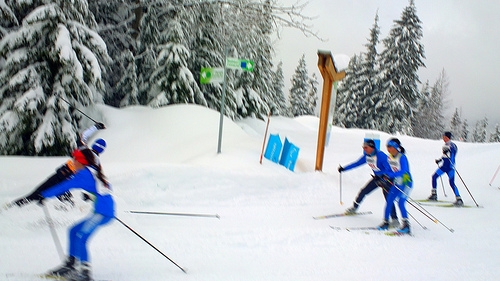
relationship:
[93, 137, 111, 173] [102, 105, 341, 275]
man falling in snow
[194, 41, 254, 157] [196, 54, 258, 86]
post with signs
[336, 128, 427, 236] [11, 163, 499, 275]
skiers on flat ground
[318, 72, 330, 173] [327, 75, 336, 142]
post with hanging sign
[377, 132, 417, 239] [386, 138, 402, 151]
skiier has blue head band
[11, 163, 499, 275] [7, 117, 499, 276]
ski race in progress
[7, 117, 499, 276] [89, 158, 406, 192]
skiers wearing vests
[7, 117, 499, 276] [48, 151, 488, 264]
skiers are in jump suits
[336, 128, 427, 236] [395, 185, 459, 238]
skiers holding ski poles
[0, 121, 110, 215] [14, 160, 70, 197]
man wearing black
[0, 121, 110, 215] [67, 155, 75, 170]
man has vest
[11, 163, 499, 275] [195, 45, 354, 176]
slope has directional signs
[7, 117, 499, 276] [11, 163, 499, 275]
people skiing in the snow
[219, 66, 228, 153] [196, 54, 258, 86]
pole with two signs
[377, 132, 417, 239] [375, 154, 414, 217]
woman wearing ski outfit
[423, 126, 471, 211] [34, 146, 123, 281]
person skiing behind person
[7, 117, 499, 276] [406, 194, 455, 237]
people holding ski poles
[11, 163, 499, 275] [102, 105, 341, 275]
ground covered with snow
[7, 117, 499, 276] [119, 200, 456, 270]
people with snow skis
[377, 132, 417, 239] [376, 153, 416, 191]
person wearing blue coat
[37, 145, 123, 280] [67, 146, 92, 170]
person with red headband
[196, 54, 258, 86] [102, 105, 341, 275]
signs posted in snow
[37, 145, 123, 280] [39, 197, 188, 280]
person with ski poles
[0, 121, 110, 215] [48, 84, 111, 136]
man with ski in air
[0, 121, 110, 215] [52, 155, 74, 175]
man wearing orange and black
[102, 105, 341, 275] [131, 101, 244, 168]
snow in a mound